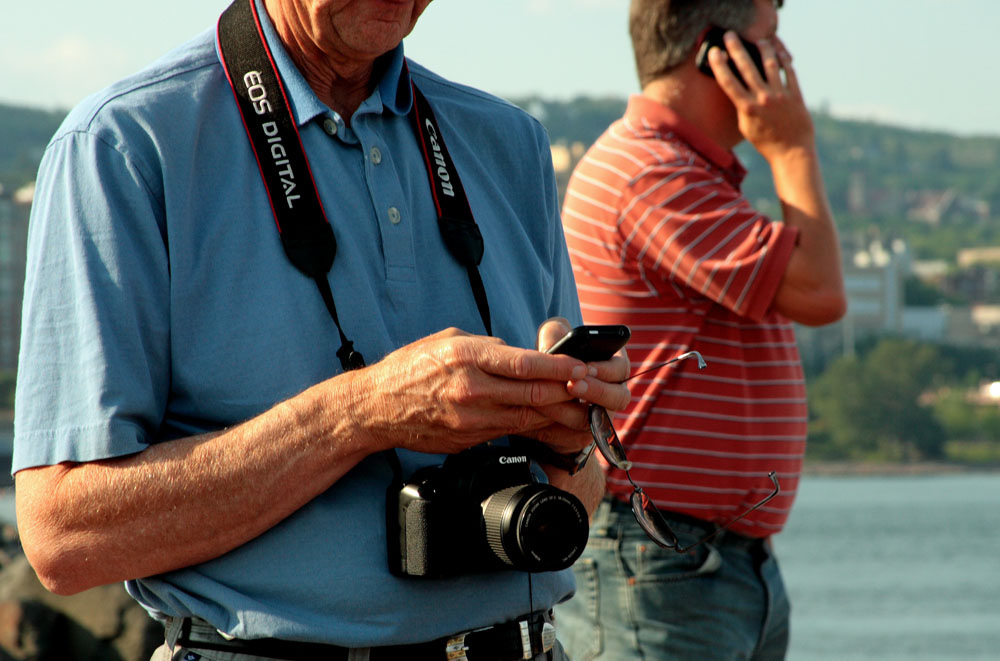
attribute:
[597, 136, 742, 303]
shirt — red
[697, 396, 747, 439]
stripes — white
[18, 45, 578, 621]
shirt — blue polo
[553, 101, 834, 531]
shirt — Red 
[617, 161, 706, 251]
stripes — white 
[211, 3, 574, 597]
strap — Black camera 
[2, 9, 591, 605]
neck — around 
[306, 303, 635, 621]
camera — Black 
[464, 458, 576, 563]
lens — large 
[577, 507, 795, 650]
jeans — blue 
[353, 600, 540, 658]
belt — Black 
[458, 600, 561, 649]
buckle — silver 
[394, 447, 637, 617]
camera — black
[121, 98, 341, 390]
shirt — blue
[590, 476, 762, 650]
jeans — blue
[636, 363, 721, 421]
shirt — red, white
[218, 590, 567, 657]
belt — black, metal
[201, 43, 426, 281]
strap — black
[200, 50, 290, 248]
boarders — red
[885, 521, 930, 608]
river — blue, calm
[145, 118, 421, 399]
shirt — blue, polo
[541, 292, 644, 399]
cellphone — black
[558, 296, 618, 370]
button — silver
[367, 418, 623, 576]
camera — black, cannon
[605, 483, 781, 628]
jeans — blue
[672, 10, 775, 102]
cellphone — black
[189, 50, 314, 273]
strap — black, white, red, camera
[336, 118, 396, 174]
button — round, white, pearl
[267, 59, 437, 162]
collar — blue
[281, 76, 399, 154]
collar — blue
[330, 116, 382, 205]
button — round, white, pearl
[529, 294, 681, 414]
phone — black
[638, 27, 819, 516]
man — striped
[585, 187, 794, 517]
shirt — red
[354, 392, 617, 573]
camera — black